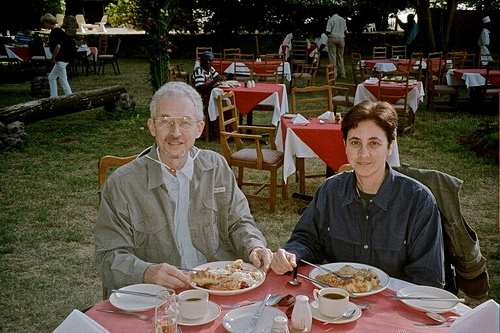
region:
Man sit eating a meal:
[97, 77, 297, 284]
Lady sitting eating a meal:
[278, 98, 445, 289]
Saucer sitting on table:
[105, 278, 170, 310]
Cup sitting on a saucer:
[168, 285, 213, 325]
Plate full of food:
[303, 257, 390, 294]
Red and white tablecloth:
[275, 115, 342, 181]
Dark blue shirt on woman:
[280, 170, 451, 295]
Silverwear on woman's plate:
[292, 252, 352, 287]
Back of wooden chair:
[213, 90, 241, 153]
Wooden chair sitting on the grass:
[212, 91, 286, 201]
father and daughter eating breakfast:
[90, 80, 445, 332]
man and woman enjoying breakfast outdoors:
[52, 80, 498, 331]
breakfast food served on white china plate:
[189, 259, 265, 294]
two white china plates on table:
[190, 259, 390, 295]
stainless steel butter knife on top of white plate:
[385, 283, 465, 312]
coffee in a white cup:
[312, 287, 350, 317]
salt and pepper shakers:
[270, 294, 312, 331]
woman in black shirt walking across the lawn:
[41, 11, 76, 95]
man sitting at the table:
[195, 51, 289, 124]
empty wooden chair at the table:
[216, 88, 288, 212]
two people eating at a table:
[65, 83, 449, 325]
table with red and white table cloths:
[244, 72, 333, 174]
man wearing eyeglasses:
[140, 78, 211, 166]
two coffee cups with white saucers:
[167, 285, 363, 323]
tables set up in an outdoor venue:
[50, 20, 488, 328]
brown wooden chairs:
[227, 79, 287, 201]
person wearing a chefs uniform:
[470, 11, 499, 72]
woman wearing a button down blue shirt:
[273, 93, 445, 290]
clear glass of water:
[152, 286, 181, 331]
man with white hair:
[127, 63, 224, 190]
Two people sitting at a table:
[113, 74, 495, 331]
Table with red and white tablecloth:
[213, 76, 301, 124]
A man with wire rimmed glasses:
[146, 107, 204, 146]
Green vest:
[413, 161, 483, 293]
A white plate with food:
[307, 258, 397, 291]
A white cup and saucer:
[306, 284, 367, 325]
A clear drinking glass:
[151, 283, 186, 331]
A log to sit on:
[6, 84, 131, 139]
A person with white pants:
[32, 13, 79, 98]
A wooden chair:
[213, 81, 286, 213]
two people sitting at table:
[98, 73, 455, 300]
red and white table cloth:
[277, 125, 329, 172]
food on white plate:
[306, 255, 386, 302]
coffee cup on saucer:
[314, 278, 358, 323]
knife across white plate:
[386, 288, 466, 309]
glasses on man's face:
[150, 109, 202, 140]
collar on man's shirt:
[137, 153, 168, 200]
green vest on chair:
[429, 166, 485, 268]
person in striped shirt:
[186, 45, 227, 94]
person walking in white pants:
[43, 46, 82, 108]